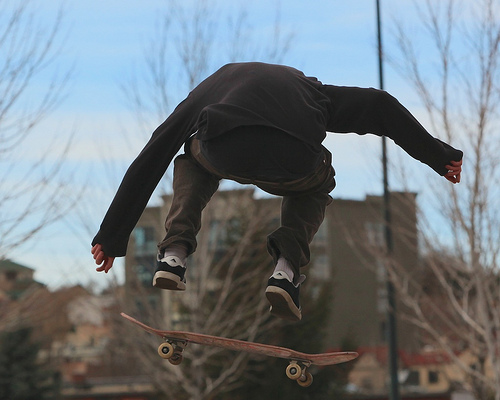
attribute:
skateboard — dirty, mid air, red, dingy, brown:
[113, 290, 362, 390]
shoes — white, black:
[138, 236, 299, 328]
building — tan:
[339, 317, 493, 390]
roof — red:
[337, 322, 464, 370]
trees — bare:
[8, 3, 213, 122]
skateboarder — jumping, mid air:
[126, 28, 471, 289]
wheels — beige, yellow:
[153, 354, 306, 396]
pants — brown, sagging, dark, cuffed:
[168, 152, 319, 258]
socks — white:
[276, 243, 309, 291]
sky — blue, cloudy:
[289, 15, 369, 53]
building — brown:
[88, 197, 429, 354]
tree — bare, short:
[404, 15, 492, 201]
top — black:
[178, 54, 414, 169]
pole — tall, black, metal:
[360, 11, 408, 239]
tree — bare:
[394, 8, 494, 303]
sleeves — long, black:
[96, 59, 211, 220]